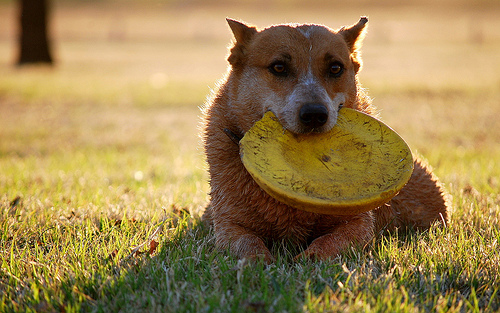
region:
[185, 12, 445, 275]
a dog laying on the ground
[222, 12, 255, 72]
the ear of a dog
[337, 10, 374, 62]
the ear of a dog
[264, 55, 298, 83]
the eye of a dog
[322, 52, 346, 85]
the eye of a dog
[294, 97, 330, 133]
a nose of a dog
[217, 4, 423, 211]
a dog with a yellow frisbee in it's mouth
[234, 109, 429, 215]
a dirty yellow frisbee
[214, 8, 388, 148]
the head of a dog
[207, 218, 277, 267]
a leg of a dog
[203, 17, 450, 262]
Dog chewing yellow frisbee while laying in grass.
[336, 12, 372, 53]
an ear of a dog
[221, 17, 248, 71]
an ear of a dog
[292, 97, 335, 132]
the nose of a dog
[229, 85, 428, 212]
a yellow frisbee in a dog's mouth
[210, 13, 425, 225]
a dog with a yellow frisbee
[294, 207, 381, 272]
the front leg of a dog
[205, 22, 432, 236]
brown dog with yellow frisbee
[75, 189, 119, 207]
short green and yellow grass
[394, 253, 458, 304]
short green and yellow grass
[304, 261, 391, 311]
short green and yellow grass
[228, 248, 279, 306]
short green and yellow grass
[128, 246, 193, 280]
short green and yellow grass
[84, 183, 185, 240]
short green and yellow grass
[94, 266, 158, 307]
short green and yellow grass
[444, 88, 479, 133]
short green and yellow grass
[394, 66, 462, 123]
short green and yellow grass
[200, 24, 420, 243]
dog has brown fur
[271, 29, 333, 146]
dog has white face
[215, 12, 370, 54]
dog has brown ears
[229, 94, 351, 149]
dog has black nose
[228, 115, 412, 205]
yellow disc in mouth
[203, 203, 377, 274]
dog has brown paws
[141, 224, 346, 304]
dark shadow on grass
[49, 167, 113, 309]
green grass near dog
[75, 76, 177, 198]
green and brown grass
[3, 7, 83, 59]
dark object in background